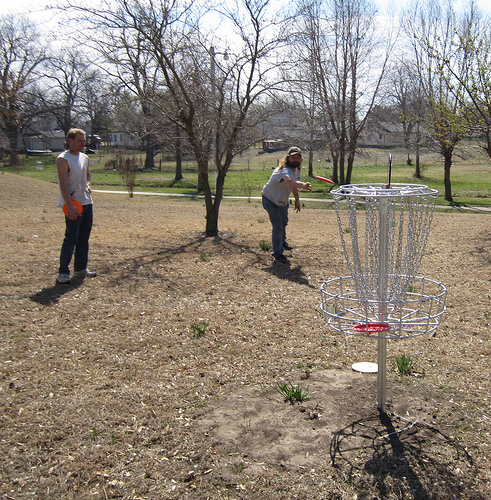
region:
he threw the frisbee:
[304, 171, 334, 195]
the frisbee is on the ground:
[343, 353, 389, 377]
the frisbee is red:
[353, 312, 392, 340]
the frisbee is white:
[349, 354, 385, 379]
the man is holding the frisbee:
[58, 195, 83, 221]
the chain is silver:
[332, 205, 355, 277]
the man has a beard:
[287, 157, 303, 171]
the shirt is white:
[71, 159, 86, 187]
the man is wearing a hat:
[283, 140, 306, 165]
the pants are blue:
[66, 227, 78, 251]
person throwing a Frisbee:
[234, 109, 366, 282]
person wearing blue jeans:
[248, 188, 298, 258]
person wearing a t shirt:
[252, 153, 310, 207]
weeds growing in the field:
[283, 369, 324, 439]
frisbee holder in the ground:
[331, 157, 442, 467]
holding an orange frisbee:
[56, 181, 96, 224]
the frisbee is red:
[306, 163, 342, 202]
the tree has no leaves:
[100, 3, 310, 218]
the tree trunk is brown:
[426, 143, 471, 210]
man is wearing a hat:
[276, 145, 308, 177]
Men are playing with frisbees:
[44, 120, 447, 416]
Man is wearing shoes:
[54, 265, 98, 286]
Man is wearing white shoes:
[53, 260, 102, 288]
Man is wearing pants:
[56, 201, 91, 273]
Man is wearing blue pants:
[55, 200, 97, 277]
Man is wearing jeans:
[55, 198, 91, 270]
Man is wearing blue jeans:
[54, 201, 95, 273]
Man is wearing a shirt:
[56, 148, 95, 209]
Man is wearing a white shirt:
[56, 145, 93, 209]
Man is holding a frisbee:
[59, 195, 87, 218]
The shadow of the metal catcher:
[327, 408, 473, 497]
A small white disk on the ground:
[351, 359, 381, 375]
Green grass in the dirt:
[278, 380, 310, 401]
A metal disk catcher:
[320, 181, 444, 336]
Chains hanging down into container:
[334, 192, 425, 314]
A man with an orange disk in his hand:
[56, 128, 99, 285]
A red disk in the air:
[315, 172, 335, 186]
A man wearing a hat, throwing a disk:
[261, 148, 305, 260]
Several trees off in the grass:
[1, 0, 476, 204]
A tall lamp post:
[205, 45, 230, 167]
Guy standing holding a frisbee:
[33, 119, 103, 312]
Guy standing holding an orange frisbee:
[22, 119, 94, 300]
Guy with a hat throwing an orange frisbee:
[238, 121, 328, 268]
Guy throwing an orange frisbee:
[248, 130, 335, 274]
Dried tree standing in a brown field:
[104, 2, 262, 381]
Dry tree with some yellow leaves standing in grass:
[380, 4, 486, 205]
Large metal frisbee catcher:
[311, 141, 459, 402]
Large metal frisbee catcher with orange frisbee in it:
[308, 110, 479, 431]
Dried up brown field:
[2, 270, 321, 493]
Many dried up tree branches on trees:
[1, 0, 428, 128]